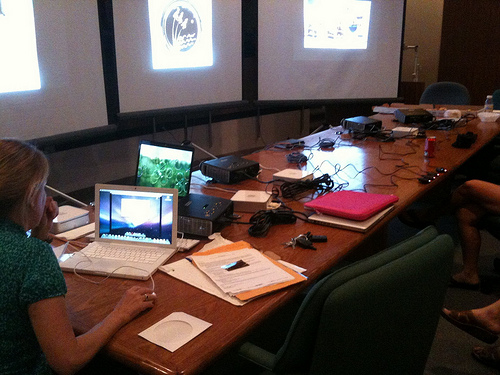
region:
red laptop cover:
[302, 182, 404, 219]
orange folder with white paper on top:
[188, 239, 308, 303]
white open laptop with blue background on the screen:
[58, 181, 182, 284]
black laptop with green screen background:
[128, 140, 196, 204]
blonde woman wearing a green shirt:
[0, 132, 160, 373]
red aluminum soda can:
[422, 134, 440, 158]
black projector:
[198, 149, 265, 186]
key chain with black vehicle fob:
[282, 225, 332, 258]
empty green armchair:
[230, 221, 460, 373]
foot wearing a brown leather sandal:
[440, 296, 499, 348]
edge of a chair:
[343, 250, 433, 312]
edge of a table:
[210, 326, 240, 346]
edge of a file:
[230, 282, 265, 297]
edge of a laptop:
[100, 266, 145, 286]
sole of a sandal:
[452, 325, 482, 346]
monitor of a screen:
[123, 211, 169, 238]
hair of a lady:
[0, 158, 37, 201]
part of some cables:
[412, 160, 440, 191]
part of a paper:
[160, 320, 205, 356]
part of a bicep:
[32, 303, 62, 341]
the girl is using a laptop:
[77, 172, 192, 294]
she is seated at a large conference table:
[13, 80, 492, 372]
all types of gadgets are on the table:
[194, 104, 469, 241]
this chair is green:
[273, 221, 444, 373]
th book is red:
[277, 170, 407, 252]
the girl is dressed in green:
[7, 231, 69, 366]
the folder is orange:
[179, 238, 301, 308]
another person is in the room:
[431, 173, 499, 341]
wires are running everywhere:
[310, 140, 417, 205]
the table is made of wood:
[350, 147, 370, 179]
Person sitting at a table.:
[6, 150, 128, 362]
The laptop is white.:
[67, 181, 169, 278]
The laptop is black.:
[126, 129, 196, 189]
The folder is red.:
[300, 187, 406, 219]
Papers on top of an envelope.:
[202, 242, 295, 312]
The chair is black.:
[280, 225, 470, 363]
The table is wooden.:
[175, 161, 386, 299]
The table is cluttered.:
[116, 99, 484, 298]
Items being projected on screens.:
[4, 5, 411, 139]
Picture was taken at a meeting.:
[6, 2, 499, 362]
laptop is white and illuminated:
[68, 174, 194, 295]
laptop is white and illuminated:
[55, 160, 263, 372]